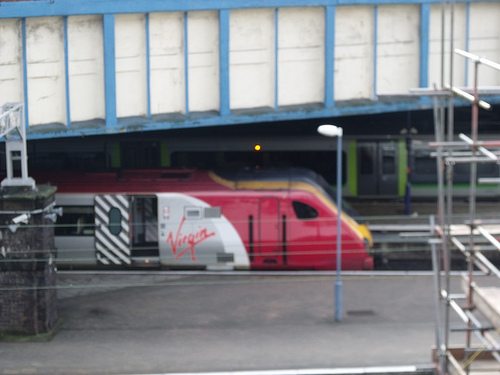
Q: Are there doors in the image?
A: Yes, there is a door.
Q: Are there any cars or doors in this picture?
A: Yes, there is a door.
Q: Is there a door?
A: Yes, there is a door.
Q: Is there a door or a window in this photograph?
A: Yes, there is a door.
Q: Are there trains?
A: Yes, there is a train.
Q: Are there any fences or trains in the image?
A: Yes, there is a train.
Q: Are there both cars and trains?
A: Yes, there are both a train and a car.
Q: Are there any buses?
A: No, there are no buses.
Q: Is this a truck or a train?
A: This is a train.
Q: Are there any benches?
A: No, there are no benches.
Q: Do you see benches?
A: No, there are no benches.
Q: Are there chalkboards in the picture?
A: No, there are no chalkboards.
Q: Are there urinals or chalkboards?
A: No, there are no chalkboards or urinals.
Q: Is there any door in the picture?
A: Yes, there is a door.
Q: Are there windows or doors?
A: Yes, there is a door.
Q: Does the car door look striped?
A: Yes, the door is striped.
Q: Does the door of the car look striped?
A: Yes, the door is striped.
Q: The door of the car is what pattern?
A: The door is striped.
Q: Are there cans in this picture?
A: No, there are no cans.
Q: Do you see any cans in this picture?
A: No, there are no cans.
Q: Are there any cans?
A: No, there are no cans.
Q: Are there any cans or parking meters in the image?
A: No, there are no cans or parking meters.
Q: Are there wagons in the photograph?
A: No, there are no wagons.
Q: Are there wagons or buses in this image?
A: No, there are no wagons or buses.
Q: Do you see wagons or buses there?
A: No, there are no wagons or buses.